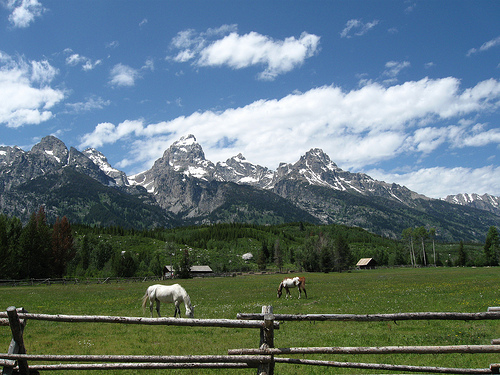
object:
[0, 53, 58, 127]
cloud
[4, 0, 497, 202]
sky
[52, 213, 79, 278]
red tree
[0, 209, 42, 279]
green trees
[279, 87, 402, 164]
clouds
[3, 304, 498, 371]
wooden fence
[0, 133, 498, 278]
mountains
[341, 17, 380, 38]
cloud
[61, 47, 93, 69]
cloud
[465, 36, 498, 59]
cloud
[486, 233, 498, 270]
trees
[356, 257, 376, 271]
house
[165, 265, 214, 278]
house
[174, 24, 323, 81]
cloud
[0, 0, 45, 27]
cloud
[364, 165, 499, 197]
cloud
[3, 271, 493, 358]
grass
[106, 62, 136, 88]
cloud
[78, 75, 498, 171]
cloud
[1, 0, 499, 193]
blue sky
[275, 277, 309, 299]
horse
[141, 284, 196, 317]
horse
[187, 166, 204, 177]
snow